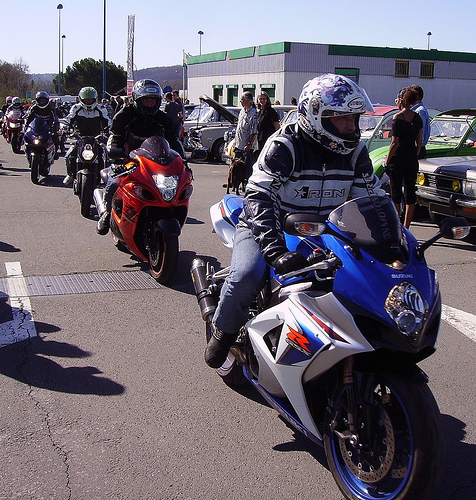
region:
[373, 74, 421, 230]
a person in the street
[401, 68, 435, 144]
a person in the street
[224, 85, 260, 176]
a person in the street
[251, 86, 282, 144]
a person in the street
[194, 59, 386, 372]
a person in the street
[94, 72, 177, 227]
a person in the street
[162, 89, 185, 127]
a person in the street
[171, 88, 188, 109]
a person in the street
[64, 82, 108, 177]
a person in the street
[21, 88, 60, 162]
a person in the street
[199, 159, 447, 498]
a blue motorcycle on the road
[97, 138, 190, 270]
a red motorcycle on the road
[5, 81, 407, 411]
a line of motorcycles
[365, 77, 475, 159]
a green vehicle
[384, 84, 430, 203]
a women with her hair in a ponytail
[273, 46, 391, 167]
a man wearing a white helmet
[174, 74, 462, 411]
a man riding his bike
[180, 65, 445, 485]
a man riding his motorcycle during the day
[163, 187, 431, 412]
a white and blue motorcycle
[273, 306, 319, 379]
orange lettering on the side of the motorcycle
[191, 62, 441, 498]
The biker at the front of the line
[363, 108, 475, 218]
The green car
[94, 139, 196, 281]
The red motorcycle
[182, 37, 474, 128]
The grey and green building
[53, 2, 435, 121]
The street lights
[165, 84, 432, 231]
The people standing next to the bikers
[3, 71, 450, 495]
The line of motorcycle riders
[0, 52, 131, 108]
The trees in the background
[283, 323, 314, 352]
The red R on the blue motorcycle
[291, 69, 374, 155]
The lead rider's helmet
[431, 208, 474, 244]
a side view mirror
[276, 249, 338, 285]
a brake handle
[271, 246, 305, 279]
a black glove on the man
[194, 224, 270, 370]
the leg of a man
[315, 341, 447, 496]
a black tire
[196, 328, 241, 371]
the black boot of a man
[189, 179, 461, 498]
a blue and white motorcycle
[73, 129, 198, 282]
a red motorcycle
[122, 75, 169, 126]
a black helmet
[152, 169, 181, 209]
a head light on the motorcycle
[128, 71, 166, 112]
the head of a person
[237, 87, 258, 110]
the head of a person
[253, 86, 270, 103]
the head of a person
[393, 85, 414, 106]
the head of a person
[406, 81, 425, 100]
the head of a person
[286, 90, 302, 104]
the head of a person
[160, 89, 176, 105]
the head of a person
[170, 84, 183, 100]
the head of a person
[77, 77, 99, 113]
the head of a person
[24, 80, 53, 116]
the head of a person